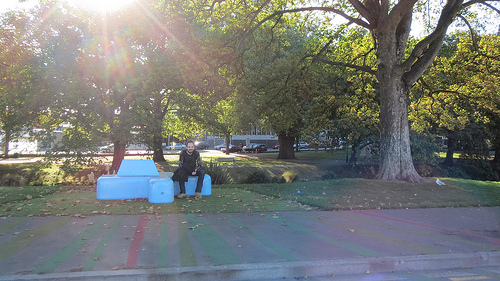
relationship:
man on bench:
[172, 140, 205, 200] [97, 152, 214, 211]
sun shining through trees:
[66, 0, 217, 85] [61, 3, 221, 137]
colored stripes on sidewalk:
[89, 216, 236, 266] [2, 204, 498, 278]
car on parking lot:
[227, 143, 273, 168] [130, 139, 328, 159]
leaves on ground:
[284, 173, 454, 223] [8, 174, 498, 224]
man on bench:
[172, 140, 205, 200] [92, 155, 217, 217]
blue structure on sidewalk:
[95, 155, 215, 202] [2, 204, 498, 278]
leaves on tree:
[312, 30, 370, 124] [330, 14, 462, 169]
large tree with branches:
[149, 0, 499, 185] [166, 0, 498, 113]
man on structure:
[172, 140, 205, 200] [95, 160, 213, 205]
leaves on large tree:
[0, 1, 497, 143] [210, 0, 499, 184]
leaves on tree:
[0, 1, 497, 143] [212, 15, 349, 160]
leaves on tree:
[0, 1, 497, 143] [21, 0, 196, 181]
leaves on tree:
[0, 1, 497, 143] [118, 0, 246, 167]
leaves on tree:
[0, 1, 497, 143] [406, 32, 499, 167]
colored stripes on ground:
[89, 216, 236, 266] [2, 139, 498, 277]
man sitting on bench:
[172, 140, 205, 200] [143, 148, 268, 216]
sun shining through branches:
[76, 3, 184, 27] [69, 7, 226, 130]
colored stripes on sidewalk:
[61, 222, 236, 266] [31, 210, 236, 270]